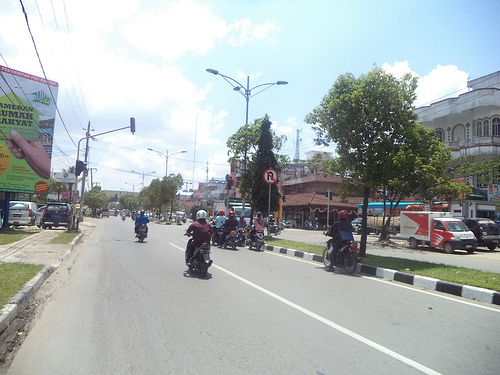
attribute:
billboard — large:
[0, 58, 77, 237]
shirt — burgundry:
[186, 221, 213, 245]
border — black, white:
[252, 241, 499, 310]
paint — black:
[361, 264, 376, 276]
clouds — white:
[86, 11, 203, 109]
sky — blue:
[109, 10, 494, 121]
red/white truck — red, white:
[396, 212, 479, 253]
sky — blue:
[93, 0, 497, 57]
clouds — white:
[1, 0, 474, 193]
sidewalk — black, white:
[263, 240, 498, 312]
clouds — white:
[83, 16, 251, 136]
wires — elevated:
[5, 3, 230, 185]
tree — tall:
[320, 76, 414, 258]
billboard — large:
[6, 79, 78, 211]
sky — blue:
[88, 57, 205, 107]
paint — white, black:
[353, 263, 437, 287]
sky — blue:
[4, 1, 494, 199]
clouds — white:
[9, 5, 276, 147]